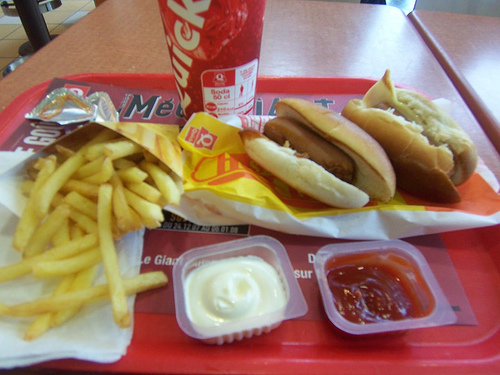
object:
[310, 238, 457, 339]
container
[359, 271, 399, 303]
ketchup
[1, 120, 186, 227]
bag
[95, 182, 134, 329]
french fries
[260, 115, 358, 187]
hotdog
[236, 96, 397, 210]
bun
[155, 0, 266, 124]
cup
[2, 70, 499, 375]
tray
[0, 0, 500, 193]
table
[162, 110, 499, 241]
bag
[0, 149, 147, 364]
napkins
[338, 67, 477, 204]
bun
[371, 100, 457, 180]
hotdog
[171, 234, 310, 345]
packet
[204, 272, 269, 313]
mayonnaise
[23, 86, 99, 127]
top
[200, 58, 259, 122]
tag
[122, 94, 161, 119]
letter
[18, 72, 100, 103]
edge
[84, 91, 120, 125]
top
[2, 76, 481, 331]
liner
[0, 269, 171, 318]
lunch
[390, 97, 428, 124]
relish